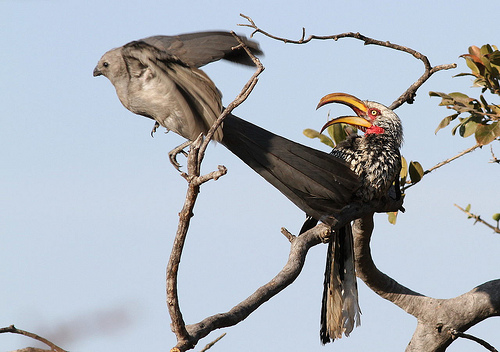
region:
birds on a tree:
[51, 23, 418, 206]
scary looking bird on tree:
[321, 85, 415, 182]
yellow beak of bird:
[325, 83, 367, 130]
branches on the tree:
[125, 190, 311, 300]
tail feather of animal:
[292, 221, 387, 342]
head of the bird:
[81, 43, 136, 90]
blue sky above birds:
[37, 151, 134, 243]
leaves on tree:
[430, 43, 497, 148]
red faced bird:
[341, 96, 408, 146]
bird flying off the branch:
[83, 21, 232, 166]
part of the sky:
[0, 76, 67, 133]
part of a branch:
[221, 267, 268, 313]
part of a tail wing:
[304, 245, 359, 302]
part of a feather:
[311, 177, 359, 222]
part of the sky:
[64, 227, 109, 267]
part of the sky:
[53, 215, 101, 273]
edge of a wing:
[326, 182, 376, 224]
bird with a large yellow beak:
[311, 87, 428, 218]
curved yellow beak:
[315, 84, 369, 139]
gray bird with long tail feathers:
[92, 28, 377, 250]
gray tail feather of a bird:
[227, 114, 365, 239]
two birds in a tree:
[82, 17, 417, 348]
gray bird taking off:
[81, 24, 376, 249]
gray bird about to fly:
[67, 28, 365, 240]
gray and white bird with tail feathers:
[298, 75, 415, 349]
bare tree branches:
[144, 178, 266, 349]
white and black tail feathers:
[317, 247, 367, 347]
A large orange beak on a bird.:
[315, 92, 373, 138]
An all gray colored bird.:
[90, 26, 264, 168]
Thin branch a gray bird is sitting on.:
[165, 33, 265, 348]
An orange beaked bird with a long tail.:
[313, 88, 404, 344]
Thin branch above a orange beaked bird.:
[237, 13, 432, 68]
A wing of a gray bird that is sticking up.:
[139, 29, 264, 69]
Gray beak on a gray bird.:
[92, 64, 101, 79]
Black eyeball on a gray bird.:
[101, 58, 110, 71]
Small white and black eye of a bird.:
[369, 106, 378, 117]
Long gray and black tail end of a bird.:
[318, 224, 362, 344]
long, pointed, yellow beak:
[313, 88, 371, 134]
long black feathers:
[218, 101, 364, 234]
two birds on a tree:
[67, 20, 444, 337]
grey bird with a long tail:
[85, 15, 381, 256]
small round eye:
[363, 101, 379, 117]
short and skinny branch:
[196, 162, 231, 187]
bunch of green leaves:
[426, 80, 497, 143]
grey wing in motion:
[123, 11, 268, 72]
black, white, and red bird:
[305, 75, 410, 343]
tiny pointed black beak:
[89, 64, 102, 80]